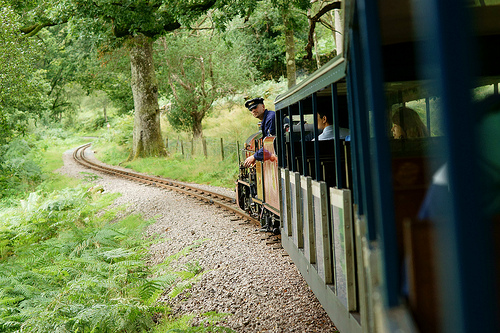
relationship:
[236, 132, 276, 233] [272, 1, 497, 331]
engine pulling train cars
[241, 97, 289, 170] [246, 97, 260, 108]
conductor has a hat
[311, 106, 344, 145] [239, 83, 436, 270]
man sitting on train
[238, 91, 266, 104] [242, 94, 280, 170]
hat worn by human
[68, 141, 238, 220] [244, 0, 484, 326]
tracks in front of train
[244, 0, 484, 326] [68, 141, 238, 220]
train behind tracks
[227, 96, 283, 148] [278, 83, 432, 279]
conductor looking behind train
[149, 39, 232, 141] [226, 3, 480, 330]
tree in front of train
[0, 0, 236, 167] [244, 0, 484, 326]
tree approaching train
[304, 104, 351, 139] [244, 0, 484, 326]
human rides train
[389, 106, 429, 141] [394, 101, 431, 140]
human wears hair